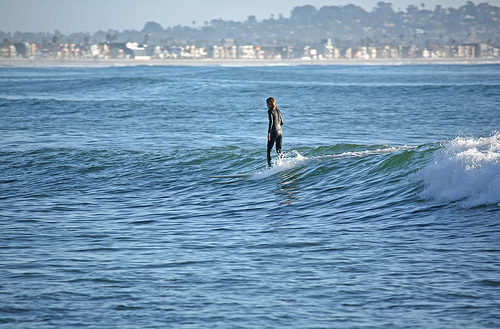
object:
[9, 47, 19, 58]
building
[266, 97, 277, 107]
head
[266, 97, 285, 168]
woman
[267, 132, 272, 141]
hand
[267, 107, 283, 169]
suit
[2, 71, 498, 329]
water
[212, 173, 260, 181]
board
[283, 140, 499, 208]
wave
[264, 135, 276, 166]
leg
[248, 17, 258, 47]
tree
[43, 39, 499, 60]
city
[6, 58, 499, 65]
shore